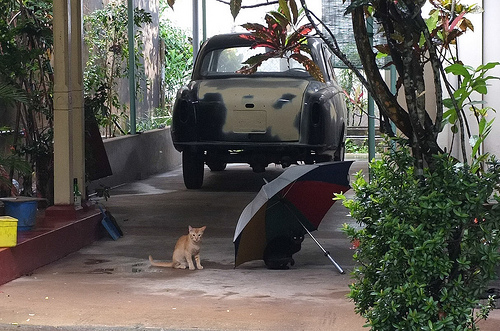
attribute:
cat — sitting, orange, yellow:
[149, 225, 207, 270]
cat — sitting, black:
[263, 230, 304, 269]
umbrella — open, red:
[233, 161, 355, 273]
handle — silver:
[326, 254, 344, 274]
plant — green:
[168, 0, 499, 330]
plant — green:
[83, 0, 151, 140]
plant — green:
[158, 19, 192, 127]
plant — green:
[0, 0, 56, 196]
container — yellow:
[0, 216, 17, 246]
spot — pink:
[241, 35, 256, 40]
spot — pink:
[300, 30, 310, 35]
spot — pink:
[272, 25, 277, 29]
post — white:
[53, 0, 87, 204]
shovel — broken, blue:
[98, 206, 119, 241]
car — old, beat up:
[171, 35, 347, 190]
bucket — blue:
[4, 201, 38, 230]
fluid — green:
[74, 179, 82, 212]